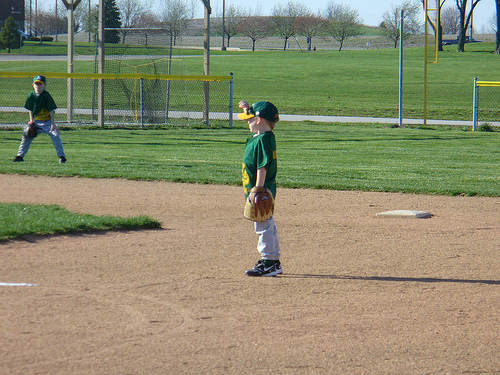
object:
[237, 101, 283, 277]
child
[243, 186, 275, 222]
glove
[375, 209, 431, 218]
base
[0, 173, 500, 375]
dirt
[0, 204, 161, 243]
grass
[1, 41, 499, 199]
grass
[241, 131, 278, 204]
jersey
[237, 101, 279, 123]
cap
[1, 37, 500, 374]
field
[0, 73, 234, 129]
fence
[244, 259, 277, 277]
cleats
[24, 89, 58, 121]
jersey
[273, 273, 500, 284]
shadow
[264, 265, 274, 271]
symbol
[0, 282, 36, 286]
line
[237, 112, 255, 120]
bill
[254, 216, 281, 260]
pants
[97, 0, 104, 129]
pole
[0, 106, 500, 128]
sidewalk